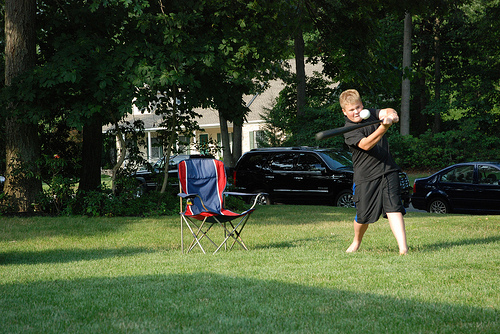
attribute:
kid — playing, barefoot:
[339, 88, 411, 255]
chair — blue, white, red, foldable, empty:
[176, 157, 269, 252]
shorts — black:
[353, 172, 405, 225]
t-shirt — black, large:
[341, 111, 401, 182]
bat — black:
[314, 116, 384, 150]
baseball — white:
[358, 108, 368, 121]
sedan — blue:
[410, 160, 499, 213]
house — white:
[102, 56, 340, 174]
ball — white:
[359, 107, 370, 122]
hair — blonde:
[341, 88, 361, 106]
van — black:
[232, 144, 412, 217]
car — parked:
[411, 163, 499, 214]